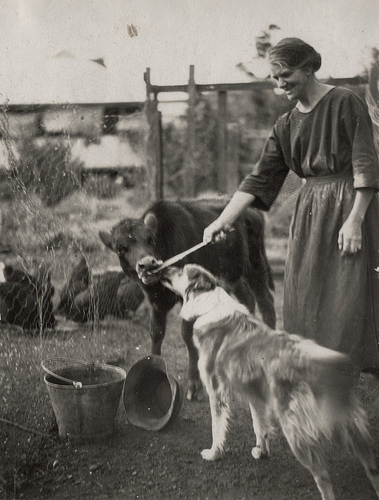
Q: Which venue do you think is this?
A: This is a farm.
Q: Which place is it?
A: It is a farm.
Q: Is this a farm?
A: Yes, it is a farm.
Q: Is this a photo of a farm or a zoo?
A: It is showing a farm.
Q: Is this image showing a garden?
A: No, the picture is showing a farm.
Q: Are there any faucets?
A: No, there are no faucets.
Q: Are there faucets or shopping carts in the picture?
A: No, there are no faucets or shopping carts.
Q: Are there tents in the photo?
A: No, there are no tents.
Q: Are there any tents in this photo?
A: No, there are no tents.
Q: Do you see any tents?
A: No, there are no tents.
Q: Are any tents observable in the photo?
A: No, there are no tents.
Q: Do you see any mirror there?
A: No, there are no mirrors.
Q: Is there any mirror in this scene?
A: No, there are no mirrors.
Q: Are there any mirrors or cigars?
A: No, there are no mirrors or cigars.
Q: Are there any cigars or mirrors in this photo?
A: No, there are no mirrors or cigars.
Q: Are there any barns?
A: No, there are no barns.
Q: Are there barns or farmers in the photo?
A: No, there are no barns or farmers.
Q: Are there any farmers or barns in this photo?
A: No, there are no barns or farmers.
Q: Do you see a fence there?
A: Yes, there is a fence.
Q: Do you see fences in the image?
A: Yes, there is a fence.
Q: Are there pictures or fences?
A: Yes, there is a fence.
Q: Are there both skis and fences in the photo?
A: No, there is a fence but no skis.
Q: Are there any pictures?
A: No, there are no pictures.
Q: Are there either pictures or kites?
A: No, there are no pictures or kites.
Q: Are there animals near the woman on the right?
A: Yes, there are animals near the woman.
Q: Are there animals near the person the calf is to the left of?
A: Yes, there are animals near the woman.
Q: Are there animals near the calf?
A: Yes, there are animals near the calf.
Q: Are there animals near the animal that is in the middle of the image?
A: Yes, there are animals near the calf.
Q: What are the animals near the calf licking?
A: The animals are licking the spoon.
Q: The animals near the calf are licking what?
A: The animals are licking the spoon.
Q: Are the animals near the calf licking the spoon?
A: Yes, the animals are licking the spoon.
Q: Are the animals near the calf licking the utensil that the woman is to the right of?
A: Yes, the animals are licking the spoon.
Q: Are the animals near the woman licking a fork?
A: No, the animals are licking the spoon.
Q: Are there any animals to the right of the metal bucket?
A: Yes, there are animals to the right of the bucket.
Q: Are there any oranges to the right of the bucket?
A: No, there are animals to the right of the bucket.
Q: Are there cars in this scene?
A: No, there are no cars.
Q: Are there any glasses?
A: No, there are no glasses.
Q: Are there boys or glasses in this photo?
A: No, there are no glasses or boys.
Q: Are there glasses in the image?
A: No, there are no glasses.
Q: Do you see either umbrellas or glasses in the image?
A: No, there are no glasses or umbrellas.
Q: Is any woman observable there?
A: Yes, there is a woman.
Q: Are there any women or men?
A: Yes, there is a woman.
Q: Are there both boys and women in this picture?
A: No, there is a woman but no boys.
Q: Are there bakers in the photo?
A: No, there are no bakers.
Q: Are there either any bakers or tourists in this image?
A: No, there are no bakers or tourists.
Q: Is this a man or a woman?
A: This is a woman.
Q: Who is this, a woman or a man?
A: This is a woman.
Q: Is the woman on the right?
A: Yes, the woman is on the right of the image.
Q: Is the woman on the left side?
A: No, the woman is on the right of the image.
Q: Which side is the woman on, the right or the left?
A: The woman is on the right of the image.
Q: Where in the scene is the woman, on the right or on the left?
A: The woman is on the right of the image.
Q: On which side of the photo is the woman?
A: The woman is on the right of the image.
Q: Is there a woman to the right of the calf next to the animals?
A: Yes, there is a woman to the right of the calf.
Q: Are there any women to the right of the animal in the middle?
A: Yes, there is a woman to the right of the calf.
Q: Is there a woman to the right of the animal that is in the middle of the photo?
A: Yes, there is a woman to the right of the calf.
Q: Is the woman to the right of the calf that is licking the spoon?
A: Yes, the woman is to the right of the calf.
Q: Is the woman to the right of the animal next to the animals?
A: Yes, the woman is to the right of the calf.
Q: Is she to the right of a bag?
A: No, the woman is to the right of the calf.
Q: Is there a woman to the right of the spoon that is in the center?
A: Yes, there is a woman to the right of the spoon.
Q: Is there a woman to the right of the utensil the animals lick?
A: Yes, there is a woman to the right of the spoon.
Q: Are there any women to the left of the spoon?
A: No, the woman is to the right of the spoon.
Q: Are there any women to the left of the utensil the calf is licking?
A: No, the woman is to the right of the spoon.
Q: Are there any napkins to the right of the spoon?
A: No, there is a woman to the right of the spoon.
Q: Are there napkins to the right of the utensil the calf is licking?
A: No, there is a woman to the right of the spoon.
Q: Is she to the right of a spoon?
A: Yes, the woman is to the right of a spoon.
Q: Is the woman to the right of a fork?
A: No, the woman is to the right of a spoon.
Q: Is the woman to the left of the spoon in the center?
A: No, the woman is to the right of the spoon.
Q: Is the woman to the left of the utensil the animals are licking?
A: No, the woman is to the right of the spoon.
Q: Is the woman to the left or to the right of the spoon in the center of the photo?
A: The woman is to the right of the spoon.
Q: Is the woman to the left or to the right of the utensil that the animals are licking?
A: The woman is to the right of the spoon.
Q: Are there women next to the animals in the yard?
A: Yes, there is a woman next to the animals.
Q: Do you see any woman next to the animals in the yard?
A: Yes, there is a woman next to the animals.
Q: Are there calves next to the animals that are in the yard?
A: Yes, there is a calf next to the animals.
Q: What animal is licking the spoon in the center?
A: The animal is a calf.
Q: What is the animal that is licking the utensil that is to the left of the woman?
A: The animal is a calf.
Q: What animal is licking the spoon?
A: The animal is a calf.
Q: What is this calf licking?
A: The calf is licking the spoon.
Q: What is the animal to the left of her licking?
A: The calf is licking the spoon.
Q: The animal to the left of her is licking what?
A: The calf is licking the spoon.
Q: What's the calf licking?
A: The calf is licking the spoon.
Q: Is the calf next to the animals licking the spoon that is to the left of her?
A: Yes, the calf is licking the spoon.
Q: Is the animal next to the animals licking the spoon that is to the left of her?
A: Yes, the calf is licking the spoon.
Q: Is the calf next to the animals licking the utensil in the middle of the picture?
A: Yes, the calf is licking the spoon.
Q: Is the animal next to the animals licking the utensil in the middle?
A: Yes, the calf is licking the spoon.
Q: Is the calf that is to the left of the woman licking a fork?
A: No, the calf is licking the spoon.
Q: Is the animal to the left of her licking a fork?
A: No, the calf is licking the spoon.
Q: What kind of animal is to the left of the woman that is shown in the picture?
A: The animal is a calf.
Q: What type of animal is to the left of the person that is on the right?
A: The animal is a calf.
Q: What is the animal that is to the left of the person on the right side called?
A: The animal is a calf.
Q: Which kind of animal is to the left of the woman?
A: The animal is a calf.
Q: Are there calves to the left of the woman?
A: Yes, there is a calf to the left of the woman.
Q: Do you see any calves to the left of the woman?
A: Yes, there is a calf to the left of the woman.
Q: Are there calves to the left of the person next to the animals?
A: Yes, there is a calf to the left of the woman.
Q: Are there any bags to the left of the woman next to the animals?
A: No, there is a calf to the left of the woman.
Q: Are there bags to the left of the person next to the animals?
A: No, there is a calf to the left of the woman.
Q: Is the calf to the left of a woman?
A: Yes, the calf is to the left of a woman.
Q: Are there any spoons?
A: Yes, there is a spoon.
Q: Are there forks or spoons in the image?
A: Yes, there is a spoon.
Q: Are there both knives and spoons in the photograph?
A: No, there is a spoon but no knives.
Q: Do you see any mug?
A: No, there are no mugs.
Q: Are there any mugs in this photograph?
A: No, there are no mugs.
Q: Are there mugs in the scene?
A: No, there are no mugs.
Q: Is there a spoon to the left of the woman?
A: Yes, there is a spoon to the left of the woman.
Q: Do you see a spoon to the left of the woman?
A: Yes, there is a spoon to the left of the woman.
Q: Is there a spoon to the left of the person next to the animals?
A: Yes, there is a spoon to the left of the woman.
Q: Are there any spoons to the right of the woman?
A: No, the spoon is to the left of the woman.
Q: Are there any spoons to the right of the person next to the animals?
A: No, the spoon is to the left of the woman.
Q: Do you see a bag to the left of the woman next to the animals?
A: No, there is a spoon to the left of the woman.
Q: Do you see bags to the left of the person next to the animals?
A: No, there is a spoon to the left of the woman.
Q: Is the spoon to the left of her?
A: Yes, the spoon is to the left of a woman.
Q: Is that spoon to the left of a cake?
A: No, the spoon is to the left of a woman.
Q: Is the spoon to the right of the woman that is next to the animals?
A: No, the spoon is to the left of the woman.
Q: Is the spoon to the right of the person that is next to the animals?
A: No, the spoon is to the left of the woman.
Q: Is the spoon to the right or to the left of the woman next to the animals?
A: The spoon is to the left of the woman.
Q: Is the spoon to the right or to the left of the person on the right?
A: The spoon is to the left of the woman.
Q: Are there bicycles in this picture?
A: No, there are no bicycles.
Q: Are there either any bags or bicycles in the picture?
A: No, there are no bicycles or bags.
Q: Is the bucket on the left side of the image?
A: Yes, the bucket is on the left of the image.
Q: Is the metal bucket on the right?
A: No, the bucket is on the left of the image.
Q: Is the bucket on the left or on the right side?
A: The bucket is on the left of the image.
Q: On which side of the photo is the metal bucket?
A: The bucket is on the left of the image.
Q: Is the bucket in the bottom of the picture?
A: Yes, the bucket is in the bottom of the image.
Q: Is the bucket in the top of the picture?
A: No, the bucket is in the bottom of the image.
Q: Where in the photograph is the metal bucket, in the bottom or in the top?
A: The bucket is in the bottom of the image.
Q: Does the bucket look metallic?
A: Yes, the bucket is metallic.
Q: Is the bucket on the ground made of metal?
A: Yes, the bucket is made of metal.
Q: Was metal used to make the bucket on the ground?
A: Yes, the bucket is made of metal.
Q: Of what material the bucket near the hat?
A: The bucket is made of metal.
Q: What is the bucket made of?
A: The bucket is made of metal.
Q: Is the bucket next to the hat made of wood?
A: No, the bucket is made of metal.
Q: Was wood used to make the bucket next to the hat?
A: No, the bucket is made of metal.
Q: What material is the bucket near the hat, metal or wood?
A: The bucket is made of metal.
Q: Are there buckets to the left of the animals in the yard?
A: Yes, there is a bucket to the left of the animals.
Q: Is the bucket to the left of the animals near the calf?
A: Yes, the bucket is to the left of the animals.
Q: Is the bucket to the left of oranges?
A: No, the bucket is to the left of the animals.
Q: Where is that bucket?
A: The bucket is on the ground.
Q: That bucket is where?
A: The bucket is on the ground.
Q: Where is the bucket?
A: The bucket is on the ground.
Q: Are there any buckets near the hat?
A: Yes, there is a bucket near the hat.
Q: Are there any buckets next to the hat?
A: Yes, there is a bucket next to the hat.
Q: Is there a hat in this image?
A: Yes, there is a hat.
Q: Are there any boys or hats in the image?
A: Yes, there is a hat.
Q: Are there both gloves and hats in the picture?
A: No, there is a hat but no gloves.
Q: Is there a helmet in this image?
A: No, there are no helmets.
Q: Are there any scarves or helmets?
A: No, there are no helmets or scarves.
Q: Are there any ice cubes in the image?
A: No, there are no ice cubes.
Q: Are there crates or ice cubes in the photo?
A: No, there are no ice cubes or crates.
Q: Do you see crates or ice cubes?
A: No, there are no ice cubes or crates.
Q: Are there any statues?
A: No, there are no statues.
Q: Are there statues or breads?
A: No, there are no statues or breads.